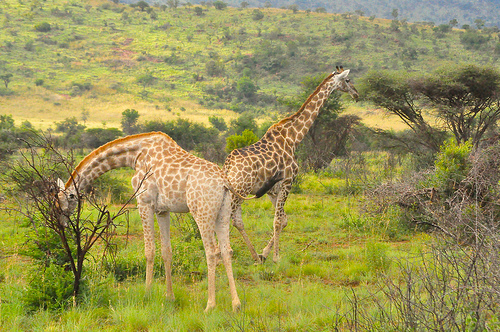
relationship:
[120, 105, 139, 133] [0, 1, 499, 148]
tree on hillside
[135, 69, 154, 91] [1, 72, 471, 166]
tree on hillside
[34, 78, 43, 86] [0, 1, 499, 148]
tree on hillside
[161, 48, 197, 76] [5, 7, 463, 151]
tree on hillside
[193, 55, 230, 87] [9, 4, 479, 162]
tree on hillside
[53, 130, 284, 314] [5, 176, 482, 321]
giraffe on plains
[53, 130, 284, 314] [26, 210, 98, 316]
giraffe grazing on leaves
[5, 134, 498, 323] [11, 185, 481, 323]
grass on ground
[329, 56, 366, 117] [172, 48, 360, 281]
giraffe head of giraffe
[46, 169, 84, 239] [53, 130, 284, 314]
giraffe head of giraffe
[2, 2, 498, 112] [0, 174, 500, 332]
hill in area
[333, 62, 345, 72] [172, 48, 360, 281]
horns on giraffe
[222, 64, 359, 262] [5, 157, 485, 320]
giraffe in area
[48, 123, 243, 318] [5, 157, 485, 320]
giraffe in area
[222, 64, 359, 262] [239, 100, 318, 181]
giraffe with spots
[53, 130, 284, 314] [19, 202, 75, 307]
giraffe eating leaves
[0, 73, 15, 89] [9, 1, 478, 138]
tree in background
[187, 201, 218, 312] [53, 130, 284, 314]
leg of giraffe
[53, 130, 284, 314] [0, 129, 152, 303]
giraffe feeding on bush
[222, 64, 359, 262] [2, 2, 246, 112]
giraffe facing hill